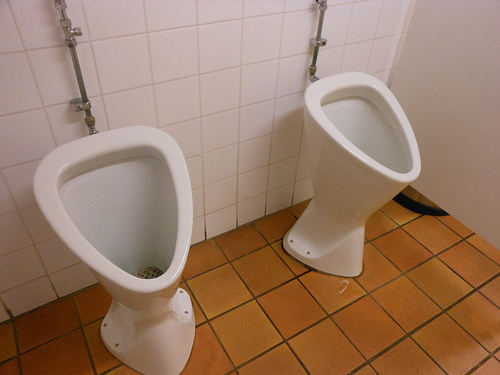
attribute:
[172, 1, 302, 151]
wall — white 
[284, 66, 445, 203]
urinal — white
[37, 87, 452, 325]
urinals — white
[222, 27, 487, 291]
toilet — white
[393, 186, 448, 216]
garbage can — silver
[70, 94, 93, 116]
bracket — chrome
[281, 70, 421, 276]
urinal — white 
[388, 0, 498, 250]
wall — white 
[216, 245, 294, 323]
tile — brown 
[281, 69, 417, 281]
toilet — white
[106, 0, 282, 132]
tiles — white 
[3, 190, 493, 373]
floor — dark, brown, tiled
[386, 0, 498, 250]
divider — white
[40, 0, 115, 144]
pole — metal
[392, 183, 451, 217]
trashcan — silver 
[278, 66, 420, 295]
urinal — white, porcelain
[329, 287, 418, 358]
tile — single, brown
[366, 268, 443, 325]
grout — brown 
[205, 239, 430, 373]
floor — brown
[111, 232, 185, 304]
drain — silver 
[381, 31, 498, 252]
stall — white 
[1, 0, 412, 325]
wall — white, tiled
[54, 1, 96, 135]
pipe — silver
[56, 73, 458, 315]
urinals — white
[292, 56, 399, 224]
urinal — white 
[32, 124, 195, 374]
urinal — white , public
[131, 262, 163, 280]
drain — stainless, steel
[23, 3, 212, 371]
urinal — white 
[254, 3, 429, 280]
urinal — white 